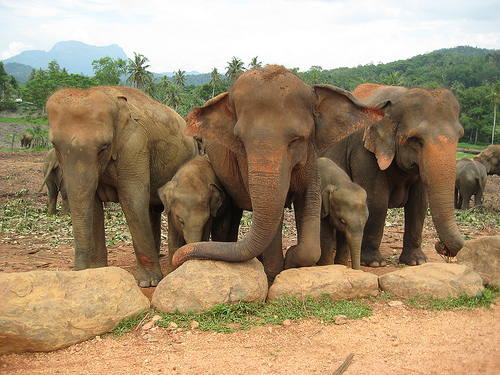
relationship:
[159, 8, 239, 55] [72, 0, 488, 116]
clouds in sky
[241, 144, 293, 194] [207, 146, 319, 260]
spot on nose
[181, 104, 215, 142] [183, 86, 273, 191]
spots on ear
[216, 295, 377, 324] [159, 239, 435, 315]
grass around rocks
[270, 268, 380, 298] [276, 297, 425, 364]
rock on ground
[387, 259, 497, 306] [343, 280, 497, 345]
rock on ground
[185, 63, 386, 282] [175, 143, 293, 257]
elephant rest trunk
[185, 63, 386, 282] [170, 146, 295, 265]
elephant with nose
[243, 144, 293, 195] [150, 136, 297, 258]
spot on trunk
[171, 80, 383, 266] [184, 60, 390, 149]
elephant with ears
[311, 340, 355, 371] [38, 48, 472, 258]
stick laying elephants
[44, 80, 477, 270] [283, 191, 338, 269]
elephants with leg